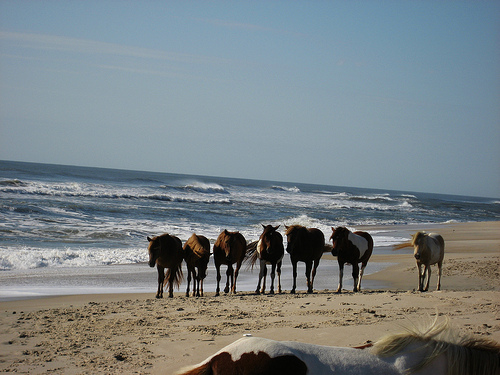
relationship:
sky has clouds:
[158, 32, 316, 118] [189, 40, 259, 113]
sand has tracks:
[175, 298, 289, 338] [97, 264, 333, 374]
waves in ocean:
[44, 161, 218, 218] [4, 119, 328, 246]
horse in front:
[369, 205, 465, 287] [130, 199, 440, 309]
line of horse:
[130, 199, 440, 309] [369, 205, 465, 287]